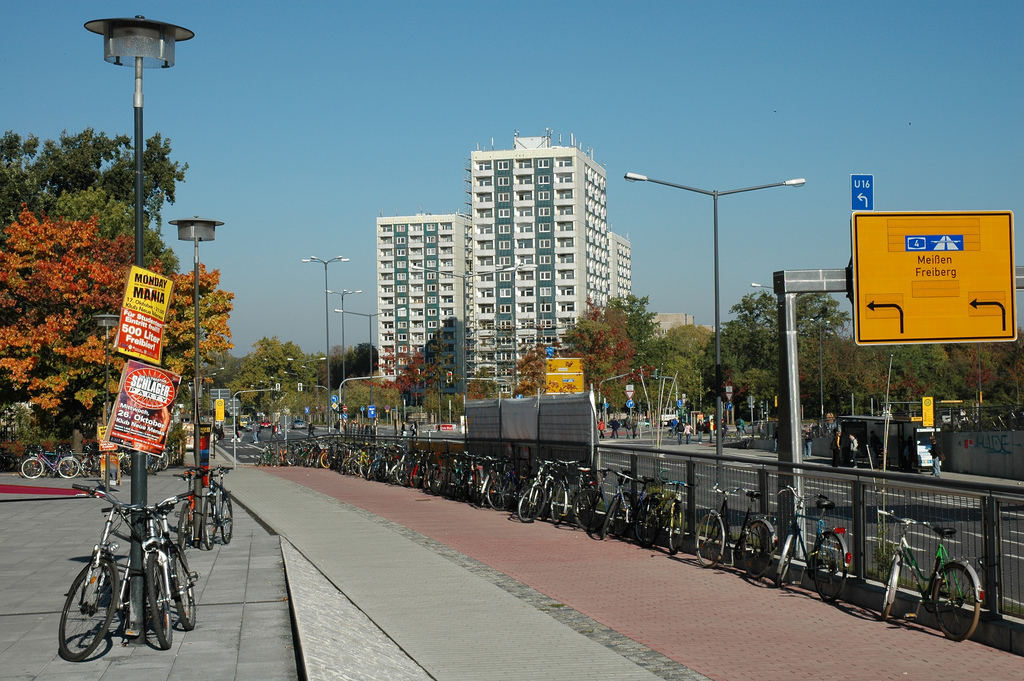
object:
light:
[622, 171, 808, 369]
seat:
[99, 502, 145, 515]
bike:
[60, 477, 151, 663]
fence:
[266, 433, 1024, 633]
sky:
[0, 2, 1024, 353]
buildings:
[373, 134, 628, 390]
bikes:
[57, 484, 200, 656]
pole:
[79, 14, 196, 619]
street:
[222, 419, 1022, 681]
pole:
[707, 195, 726, 359]